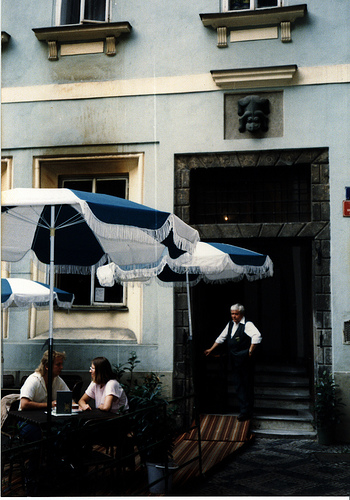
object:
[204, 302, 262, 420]
man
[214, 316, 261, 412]
uniform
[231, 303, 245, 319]
hair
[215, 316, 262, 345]
shirt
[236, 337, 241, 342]
vest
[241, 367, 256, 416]
pants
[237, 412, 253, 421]
shoe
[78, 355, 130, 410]
person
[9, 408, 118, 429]
table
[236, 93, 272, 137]
statue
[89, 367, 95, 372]
glasses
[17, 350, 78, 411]
man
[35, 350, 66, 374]
hair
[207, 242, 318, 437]
doorway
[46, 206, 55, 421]
pole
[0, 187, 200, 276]
umbrella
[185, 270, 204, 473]
pole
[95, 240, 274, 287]
umbrella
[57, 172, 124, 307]
window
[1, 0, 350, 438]
building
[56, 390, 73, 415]
menu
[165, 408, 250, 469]
rug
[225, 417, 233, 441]
stripe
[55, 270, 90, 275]
fringe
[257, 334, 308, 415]
stairway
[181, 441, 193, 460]
stripe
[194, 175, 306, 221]
window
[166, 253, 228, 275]
panel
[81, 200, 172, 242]
panel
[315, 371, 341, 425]
plant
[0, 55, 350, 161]
wall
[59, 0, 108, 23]
window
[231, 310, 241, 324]
head